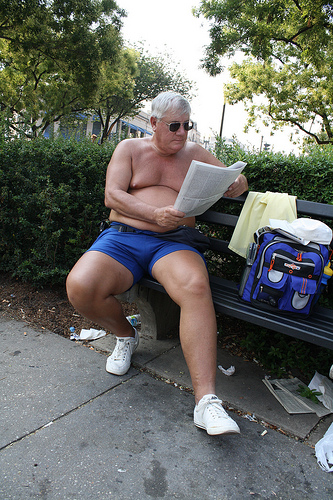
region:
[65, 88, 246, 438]
Silver hair man in shorts reading.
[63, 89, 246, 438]
Topless man sitting on bench.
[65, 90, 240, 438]
Topless man in blue shorts.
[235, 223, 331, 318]
Blue and grey bag on bench.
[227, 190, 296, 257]
Yellow shirt folded on bench.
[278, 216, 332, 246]
White cap sitting on blue bag.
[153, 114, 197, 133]
Sunglasses worn by man on bench.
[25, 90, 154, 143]
Grey building with blue awnings.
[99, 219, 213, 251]
Dark blue fanny pack worn by man.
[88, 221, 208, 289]
Blue shorts worn by man on bench.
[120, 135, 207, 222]
The man is shirtless.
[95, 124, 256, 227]
The man is reading newspaper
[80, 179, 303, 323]
The man is sitting on bench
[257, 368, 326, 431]
Newspaper under the bench.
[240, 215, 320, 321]
A bag sitting on bench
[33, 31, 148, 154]
Trees in behind bench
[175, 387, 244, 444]
Man is wearing white sneakers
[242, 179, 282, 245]
Shirt hanging on bench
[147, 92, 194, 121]
Man has gray hair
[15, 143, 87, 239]
Bushes are green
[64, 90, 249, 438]
a man reading a newspaper on a park bench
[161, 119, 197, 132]
sunglasses on the mans face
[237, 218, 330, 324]
a backpack with the man's contents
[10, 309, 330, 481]
trash disguarded on the pavement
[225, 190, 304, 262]
a yellow shirt resting on the bench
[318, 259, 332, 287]
a yellow and blue water bottle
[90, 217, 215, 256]
a fanny pack around the man's waist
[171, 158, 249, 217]
a newspaper being read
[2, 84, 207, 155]
a building with blue awnings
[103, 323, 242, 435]
white athletic shoes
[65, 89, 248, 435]
Shirtless man sitting on bench reading newspaper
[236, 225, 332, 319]
Blue backpack on bench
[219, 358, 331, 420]
Paper and litter on the ground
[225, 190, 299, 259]
Yellow shirt draped over bench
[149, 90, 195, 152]
Sunglasses on man's eyes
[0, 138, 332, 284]
Bushes behind the bench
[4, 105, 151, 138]
Building behind the trees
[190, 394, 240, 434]
White tennis shoe on man's foot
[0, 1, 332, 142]
Trees behind the man and bench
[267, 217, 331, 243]
White cap on top of backpack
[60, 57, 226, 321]
white haired man reading newspaper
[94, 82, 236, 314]
man without shirt sitting on park bench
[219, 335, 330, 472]
trash on the ground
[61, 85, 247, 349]
man in blue shorts sitting on bench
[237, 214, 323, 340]
backpack sitting on park bench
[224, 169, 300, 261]
yellow shirt draped on back of bench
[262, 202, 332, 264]
white cap laying on backpack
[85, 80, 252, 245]
shirt less man reading a newspaper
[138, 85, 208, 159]
white haired man wearing sunglasses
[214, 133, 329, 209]
green shrubbery behind park bench